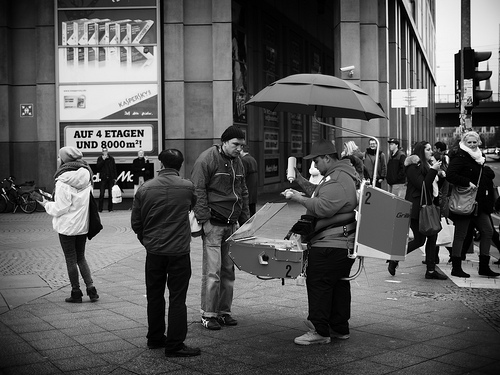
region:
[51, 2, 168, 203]
poster on exterior of commercial building wall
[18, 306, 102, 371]
brick tile sidewalk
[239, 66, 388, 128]
umbrella strapped to hot dog merchant's back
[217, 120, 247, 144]
balck knit cap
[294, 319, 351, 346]
pair of white sneakers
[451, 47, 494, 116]
black three part traffic light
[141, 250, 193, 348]
pair of black pants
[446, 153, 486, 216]
brown pocket book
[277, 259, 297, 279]
number on side of portable hot dog stand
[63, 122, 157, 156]
black and white letters on poster on side of exterior wall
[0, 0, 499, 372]
A black and white photograph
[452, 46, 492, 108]
A multi colored street light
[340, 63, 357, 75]
A rear facing surveillance camera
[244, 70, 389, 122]
a several layered umbrella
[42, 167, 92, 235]
white large fluffy jacket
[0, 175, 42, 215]
an old fashioned bicycle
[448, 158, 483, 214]
a big wrinkled satchel purse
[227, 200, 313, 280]
a holding station for food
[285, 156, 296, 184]
a squeeze type condiment bottle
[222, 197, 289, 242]
clear plastic type of lid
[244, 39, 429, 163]
the umbrella is open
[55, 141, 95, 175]
woman is wearing a hat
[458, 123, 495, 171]
woman wearing a scarf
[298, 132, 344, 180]
man wearing a hat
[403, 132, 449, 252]
woman carrying a purse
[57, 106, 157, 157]
sign is in foreign lanuage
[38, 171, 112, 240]
woman's jacket is white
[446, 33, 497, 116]
street light is black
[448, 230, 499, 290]
woman is wearing boots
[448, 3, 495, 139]
streetlight is attached to pole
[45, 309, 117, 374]
this is a pavement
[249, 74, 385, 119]
this is an umbrella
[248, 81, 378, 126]
the umbrella is open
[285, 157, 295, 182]
this is a container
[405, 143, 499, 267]
these are two women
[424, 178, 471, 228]
these are two handbags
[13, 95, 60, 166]
this is a wall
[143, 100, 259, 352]
the people are standing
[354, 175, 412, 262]
the object is metallic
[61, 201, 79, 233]
the object is white in color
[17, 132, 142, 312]
Woman with white coat and jeans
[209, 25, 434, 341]
Walking hot dog stand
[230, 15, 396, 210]
Umbrella over man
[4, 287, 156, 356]
Tile covered patio area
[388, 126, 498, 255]
Two women talking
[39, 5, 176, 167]
Huge sign advertisment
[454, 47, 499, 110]
Three light traffic light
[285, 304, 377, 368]
Men's white hightop tennis shoes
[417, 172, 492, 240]
Two womens purses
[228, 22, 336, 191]
Large entrance for entertainment attraction